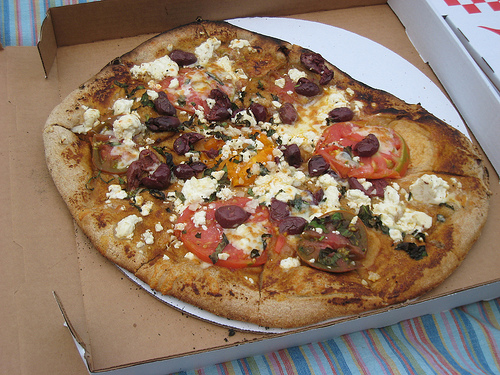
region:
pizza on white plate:
[67, 35, 436, 300]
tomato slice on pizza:
[197, 219, 248, 281]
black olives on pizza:
[165, 90, 232, 141]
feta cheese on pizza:
[368, 188, 418, 243]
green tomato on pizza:
[389, 131, 424, 177]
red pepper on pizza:
[212, 135, 321, 151]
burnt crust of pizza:
[240, 28, 310, 65]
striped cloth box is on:
[394, 328, 446, 368]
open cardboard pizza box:
[13, 266, 72, 336]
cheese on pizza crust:
[139, 261, 205, 306]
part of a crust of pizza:
[42, 85, 102, 247]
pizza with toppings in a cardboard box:
[36, 29, 496, 366]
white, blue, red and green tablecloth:
[380, 325, 497, 370]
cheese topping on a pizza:
[377, 173, 452, 246]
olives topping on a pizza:
[280, 50, 362, 121]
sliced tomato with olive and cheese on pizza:
[180, 195, 277, 267]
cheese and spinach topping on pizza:
[355, 204, 432, 261]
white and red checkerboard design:
[440, 0, 497, 27]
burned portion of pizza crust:
[348, 82, 439, 119]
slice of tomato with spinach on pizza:
[296, 208, 370, 270]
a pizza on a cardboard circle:
[36, 33, 494, 355]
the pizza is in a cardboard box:
[2, 2, 499, 372]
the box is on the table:
[4, 2, 494, 372]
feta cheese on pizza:
[78, 37, 452, 268]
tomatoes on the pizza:
[148, 61, 412, 281]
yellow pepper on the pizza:
[182, 127, 277, 200]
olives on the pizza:
[121, 35, 403, 250]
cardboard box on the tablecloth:
[0, 1, 495, 372]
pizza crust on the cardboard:
[37, 23, 497, 333]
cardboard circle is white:
[52, 18, 497, 337]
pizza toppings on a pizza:
[42, 46, 496, 242]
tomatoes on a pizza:
[322, 95, 429, 200]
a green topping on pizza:
[305, 203, 392, 310]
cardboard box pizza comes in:
[1, 248, 178, 370]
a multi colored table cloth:
[288, 343, 495, 363]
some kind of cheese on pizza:
[94, 93, 261, 250]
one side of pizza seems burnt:
[121, 20, 331, 70]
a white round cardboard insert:
[252, 13, 462, 133]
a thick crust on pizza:
[127, 218, 364, 322]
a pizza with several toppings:
[35, 14, 485, 264]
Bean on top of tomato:
[352, 130, 380, 163]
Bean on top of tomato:
[213, 198, 248, 233]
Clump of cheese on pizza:
[132, 54, 181, 76]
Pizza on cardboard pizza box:
[52, 17, 489, 326]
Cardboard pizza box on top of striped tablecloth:
[0, 0, 499, 374]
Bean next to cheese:
[305, 151, 327, 179]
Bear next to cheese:
[171, 161, 194, 178]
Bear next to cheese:
[168, 48, 200, 63]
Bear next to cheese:
[290, 71, 324, 97]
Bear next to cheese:
[146, 116, 180, 131]